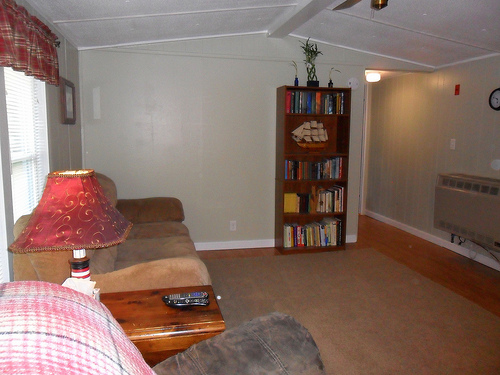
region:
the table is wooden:
[30, 111, 302, 365]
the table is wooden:
[111, 151, 228, 368]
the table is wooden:
[57, 156, 188, 336]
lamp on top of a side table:
[14, 166, 130, 302]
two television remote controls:
[151, 289, 212, 311]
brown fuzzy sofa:
[37, 176, 191, 282]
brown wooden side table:
[96, 280, 228, 347]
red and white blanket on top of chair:
[7, 276, 132, 373]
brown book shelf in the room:
[260, 66, 367, 254]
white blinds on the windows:
[2, 79, 53, 217]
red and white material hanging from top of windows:
[0, 11, 67, 69]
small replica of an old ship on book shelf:
[287, 119, 332, 153]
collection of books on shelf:
[287, 220, 344, 252]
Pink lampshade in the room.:
[7, 165, 147, 255]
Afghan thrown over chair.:
[0, 277, 150, 374]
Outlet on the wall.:
[228, 216, 241, 232]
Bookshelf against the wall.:
[273, 81, 353, 256]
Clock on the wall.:
[484, 83, 497, 111]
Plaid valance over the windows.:
[0, 2, 65, 87]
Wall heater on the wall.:
[431, 168, 499, 250]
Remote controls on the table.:
[161, 287, 213, 309]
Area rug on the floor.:
[201, 251, 499, 373]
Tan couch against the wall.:
[11, 181, 210, 289]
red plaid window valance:
[0, 0, 68, 94]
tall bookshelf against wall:
[269, 76, 355, 258]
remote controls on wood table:
[157, 288, 214, 314]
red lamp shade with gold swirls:
[3, 158, 139, 260]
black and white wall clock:
[483, 84, 498, 113]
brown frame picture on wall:
[51, 71, 82, 129]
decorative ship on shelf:
[285, 113, 342, 157]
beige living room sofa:
[2, 166, 228, 293]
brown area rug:
[195, 250, 497, 373]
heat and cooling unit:
[421, 152, 496, 274]